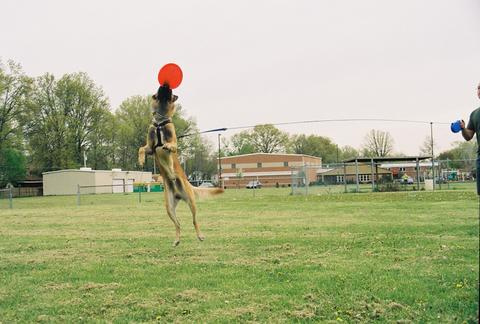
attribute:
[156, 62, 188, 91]
frisbee — red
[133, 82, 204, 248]
dog — jumping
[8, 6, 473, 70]
clouds — white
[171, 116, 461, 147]
leash — black, blue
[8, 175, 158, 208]
fence — brown, chain link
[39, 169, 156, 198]
building — beige, open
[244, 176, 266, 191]
car — parked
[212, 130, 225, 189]
pole — metal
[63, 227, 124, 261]
grass — green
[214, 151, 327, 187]
building — brick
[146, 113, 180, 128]
collar — black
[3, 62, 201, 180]
trees — green